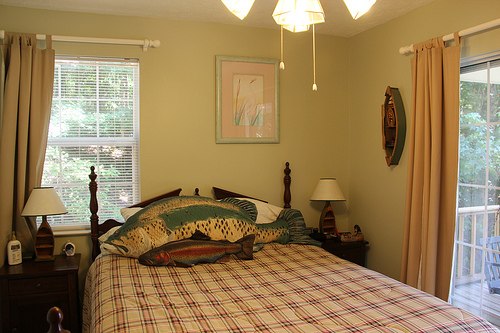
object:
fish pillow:
[139, 229, 256, 266]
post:
[282, 161, 292, 209]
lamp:
[309, 179, 348, 240]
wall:
[0, 5, 347, 309]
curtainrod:
[396, 17, 499, 56]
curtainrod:
[0, 27, 160, 49]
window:
[447, 51, 499, 329]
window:
[32, 145, 143, 228]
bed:
[77, 160, 498, 333]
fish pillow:
[99, 194, 323, 257]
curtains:
[402, 31, 459, 304]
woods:
[457, 204, 499, 216]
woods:
[453, 240, 499, 253]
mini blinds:
[35, 59, 139, 229]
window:
[46, 58, 140, 139]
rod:
[0, 30, 160, 49]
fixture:
[339, 0, 379, 22]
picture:
[213, 52, 281, 143]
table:
[0, 252, 84, 333]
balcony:
[455, 204, 499, 328]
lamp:
[12, 188, 71, 260]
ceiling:
[1, 0, 433, 38]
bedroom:
[0, 0, 499, 333]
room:
[0, 0, 499, 333]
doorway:
[440, 54, 497, 332]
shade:
[308, 200, 347, 212]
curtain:
[0, 32, 55, 261]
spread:
[80, 241, 499, 333]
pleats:
[424, 48, 442, 296]